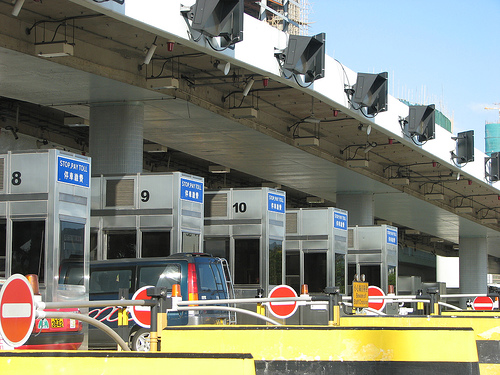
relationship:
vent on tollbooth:
[92, 174, 145, 208] [95, 154, 193, 263]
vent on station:
[200, 189, 234, 219] [203, 187, 288, 326]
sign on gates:
[266, 282, 298, 320] [31, 293, 458, 333]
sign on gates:
[266, 282, 298, 320] [14, 285, 494, 319]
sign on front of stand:
[56, 145, 105, 190] [35, 191, 92, 292]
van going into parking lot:
[97, 259, 227, 317] [1, 114, 53, 156]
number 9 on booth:
[137, 180, 154, 208] [112, 171, 180, 244]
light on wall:
[399, 100, 441, 148] [384, 90, 413, 130]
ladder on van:
[214, 249, 244, 324] [106, 255, 214, 320]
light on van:
[185, 261, 200, 315] [89, 240, 225, 315]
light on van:
[181, 259, 201, 315] [95, 256, 228, 332]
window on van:
[95, 265, 128, 292] [85, 256, 238, 320]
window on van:
[135, 264, 174, 290] [85, 256, 238, 320]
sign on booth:
[171, 171, 207, 202] [95, 172, 205, 291]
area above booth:
[167, 103, 444, 231] [110, 165, 189, 264]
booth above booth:
[110, 165, 189, 264] [207, 182, 287, 285]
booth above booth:
[110, 165, 189, 264] [284, 205, 350, 284]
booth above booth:
[110, 165, 189, 264] [350, 216, 413, 297]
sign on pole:
[132, 284, 167, 324] [145, 287, 317, 305]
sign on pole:
[268, 281, 297, 311] [283, 286, 431, 303]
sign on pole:
[355, 279, 387, 309] [356, 297, 486, 305]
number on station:
[228, 199, 246, 215] [205, 187, 286, 294]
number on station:
[9, 169, 23, 189] [15, 152, 94, 307]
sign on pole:
[475, 287, 486, 316] [450, 297, 485, 314]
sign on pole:
[258, 278, 321, 328] [272, 290, 382, 313]